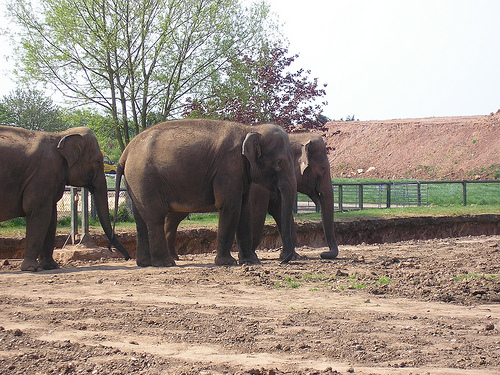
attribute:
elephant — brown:
[118, 112, 296, 264]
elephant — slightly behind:
[4, 119, 129, 269]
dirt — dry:
[6, 247, 497, 374]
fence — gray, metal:
[60, 181, 499, 211]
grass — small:
[3, 176, 499, 248]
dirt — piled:
[406, 253, 499, 309]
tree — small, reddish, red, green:
[229, 40, 340, 174]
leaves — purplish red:
[237, 51, 321, 121]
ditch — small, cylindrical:
[1, 205, 500, 278]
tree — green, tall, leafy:
[60, 106, 134, 171]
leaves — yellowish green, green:
[71, 107, 122, 157]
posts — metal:
[67, 184, 91, 240]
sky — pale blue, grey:
[0, 3, 499, 113]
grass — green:
[282, 260, 495, 299]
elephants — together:
[2, 111, 337, 267]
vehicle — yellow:
[101, 153, 118, 175]